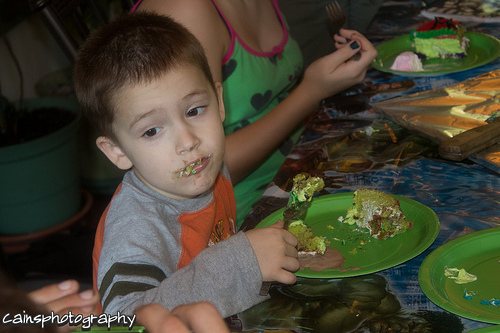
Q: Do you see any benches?
A: No, there are no benches.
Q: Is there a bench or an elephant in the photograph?
A: No, there are no benches or elephants.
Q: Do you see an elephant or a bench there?
A: No, there are no benches or elephants.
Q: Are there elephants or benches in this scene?
A: No, there are no benches or elephants.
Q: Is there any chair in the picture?
A: No, there are no chairs.